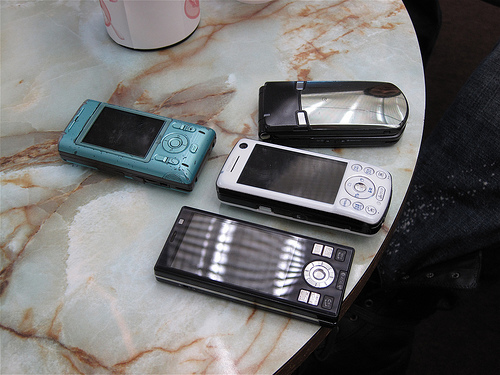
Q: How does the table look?
A: The table looks nice and shiny.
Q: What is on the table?
A: Electronic devices are on the table.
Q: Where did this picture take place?
A: It took place at someones house.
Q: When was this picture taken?
A: It was taken in the day time.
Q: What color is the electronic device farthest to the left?
A: The device is blue.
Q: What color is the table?
A: The table is brown and white.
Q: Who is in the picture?
A: Nobody is in the picture.